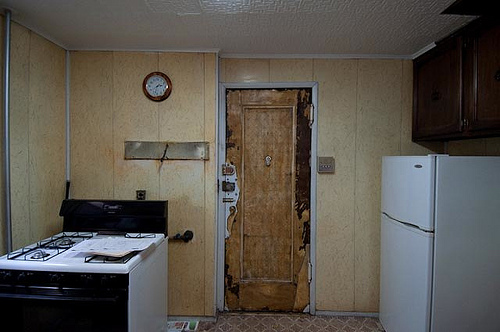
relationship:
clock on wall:
[116, 62, 195, 95] [116, 53, 247, 157]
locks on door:
[205, 159, 238, 199] [216, 75, 352, 287]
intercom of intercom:
[317, 156, 336, 175] [296, 137, 371, 199]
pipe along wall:
[53, 91, 85, 149] [116, 53, 247, 157]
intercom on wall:
[317, 156, 336, 175] [116, 53, 247, 157]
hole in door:
[242, 139, 285, 177] [216, 75, 352, 287]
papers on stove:
[76, 241, 155, 264] [48, 218, 137, 265]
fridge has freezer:
[385, 133, 489, 298] [382, 157, 456, 215]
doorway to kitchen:
[218, 89, 334, 320] [57, 45, 437, 240]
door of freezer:
[372, 163, 404, 190] [382, 157, 456, 215]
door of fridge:
[372, 163, 404, 190] [385, 133, 489, 298]